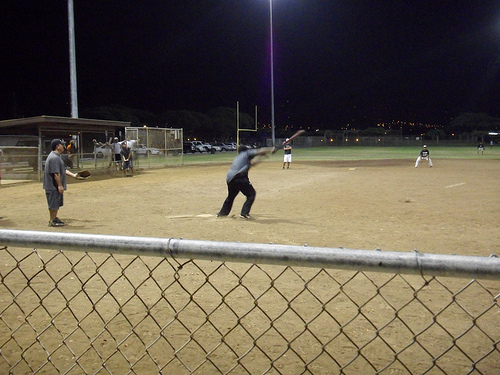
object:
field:
[0, 160, 499, 374]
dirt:
[0, 157, 499, 374]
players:
[40, 137, 92, 228]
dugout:
[0, 114, 133, 166]